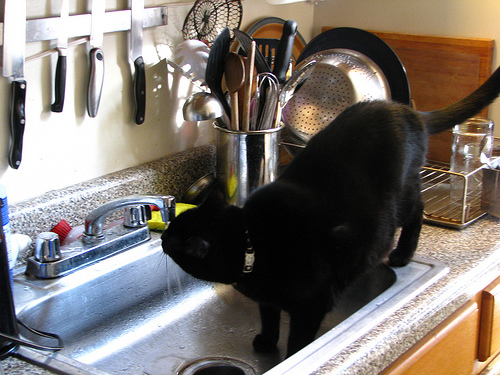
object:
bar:
[0, 1, 170, 47]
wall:
[0, 0, 313, 218]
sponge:
[149, 201, 201, 229]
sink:
[14, 227, 399, 373]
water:
[159, 257, 187, 314]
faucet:
[77, 190, 181, 241]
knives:
[48, 0, 72, 113]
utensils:
[166, 55, 222, 96]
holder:
[210, 120, 286, 208]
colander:
[282, 46, 396, 151]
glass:
[443, 114, 494, 211]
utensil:
[219, 51, 249, 130]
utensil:
[237, 34, 256, 135]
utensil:
[268, 17, 298, 131]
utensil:
[201, 24, 239, 126]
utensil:
[253, 70, 283, 129]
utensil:
[183, 89, 231, 130]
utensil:
[124, 0, 154, 128]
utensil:
[79, 0, 105, 123]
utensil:
[47, 0, 75, 115]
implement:
[1, 1, 31, 170]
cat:
[152, 65, 500, 363]